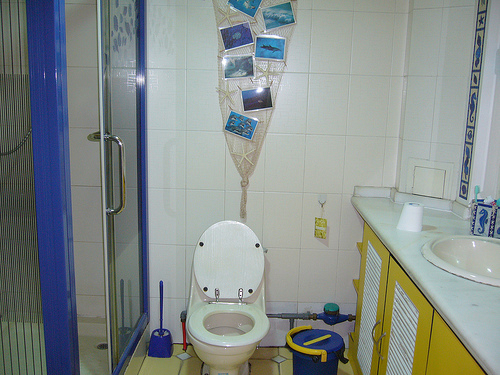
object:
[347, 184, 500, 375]
vanity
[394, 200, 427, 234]
toilet paper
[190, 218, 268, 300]
toilet lid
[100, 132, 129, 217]
handle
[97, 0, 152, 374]
door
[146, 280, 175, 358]
toilet brush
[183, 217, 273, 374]
toilet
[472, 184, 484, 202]
toothbrush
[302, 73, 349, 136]
tiles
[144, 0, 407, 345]
wall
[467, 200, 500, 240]
cup